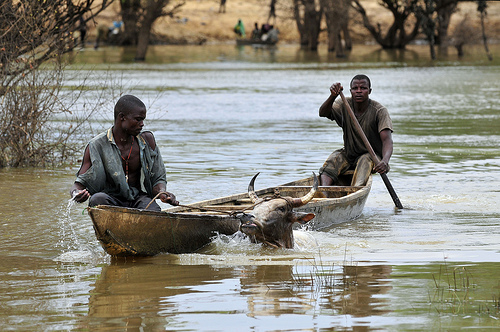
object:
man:
[314, 73, 393, 190]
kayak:
[86, 160, 373, 257]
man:
[67, 94, 177, 215]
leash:
[142, 193, 293, 217]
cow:
[236, 171, 318, 252]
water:
[1, 64, 499, 329]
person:
[250, 20, 264, 40]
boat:
[235, 34, 273, 47]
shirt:
[112, 24, 118, 31]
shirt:
[235, 26, 243, 33]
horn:
[244, 171, 265, 204]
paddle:
[336, 83, 403, 212]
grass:
[426, 263, 497, 325]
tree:
[1, 0, 114, 167]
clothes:
[74, 126, 167, 212]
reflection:
[236, 261, 391, 324]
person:
[233, 18, 242, 44]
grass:
[225, 31, 243, 40]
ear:
[294, 211, 318, 226]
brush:
[0, 69, 104, 173]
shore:
[0, 6, 500, 59]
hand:
[71, 188, 92, 203]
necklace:
[110, 131, 137, 183]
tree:
[118, 0, 183, 61]